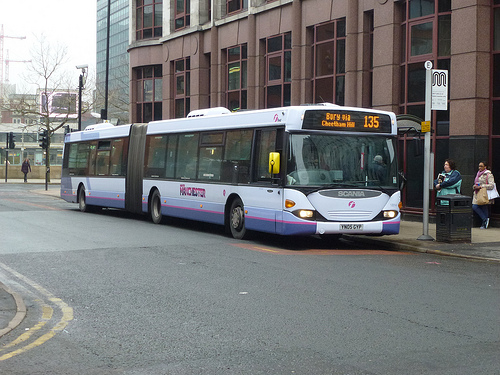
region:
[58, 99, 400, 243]
bus is stretched city bus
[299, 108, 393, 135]
bus has digital readout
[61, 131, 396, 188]
windows on bus reflecting surroundings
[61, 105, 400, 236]
white pink and purple bus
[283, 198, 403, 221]
two headlights lit on bus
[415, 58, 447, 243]
signpost has banner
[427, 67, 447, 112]
white banner with m on it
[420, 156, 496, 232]
people walking to bus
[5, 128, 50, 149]
black stoplights hang above street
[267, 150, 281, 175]
yellow side view mirror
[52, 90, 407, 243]
long bus on city street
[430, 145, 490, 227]
people standing on sidewalk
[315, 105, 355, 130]
destination on front of bus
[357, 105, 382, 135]
orange numbers on bus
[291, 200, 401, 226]
glowing headlights on bus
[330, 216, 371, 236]
license plate on front of bus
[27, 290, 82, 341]
yellow curved line in road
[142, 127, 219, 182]
windows on side of bus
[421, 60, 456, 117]
sign on metal pole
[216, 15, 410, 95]
windows on red building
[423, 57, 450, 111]
White Bus stop sign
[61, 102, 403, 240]
an extra long city bus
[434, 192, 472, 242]
a city trash receptacle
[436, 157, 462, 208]
a woman with dark hair standing by the bus stop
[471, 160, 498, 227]
a woman wearing a tan jacket and scarf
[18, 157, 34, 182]
a woman walking in the distance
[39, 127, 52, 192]
a traffic light in the distance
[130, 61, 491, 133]
a red brick building behind the bus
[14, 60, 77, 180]
a leafless tree in the background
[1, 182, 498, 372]
a city street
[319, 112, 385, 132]
digital route number sign on bus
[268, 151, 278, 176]
yellow mirror on bus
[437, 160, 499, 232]
two people waiting at bus stop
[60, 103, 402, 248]
purple and white double-length bus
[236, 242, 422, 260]
red bus lane marking in front of bus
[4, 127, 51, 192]
two traffic lights behind bus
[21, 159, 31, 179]
person walking behind the bus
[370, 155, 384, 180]
bus driver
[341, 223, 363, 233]
license plate on front of bus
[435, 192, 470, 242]
trash can at bus stop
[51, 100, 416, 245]
a bus park on side of road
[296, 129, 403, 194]
windshield of bus is large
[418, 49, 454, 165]
a pole with a sign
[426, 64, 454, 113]
a white sign on a pole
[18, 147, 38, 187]
a person walking on sidewalk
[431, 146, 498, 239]
two people in a bus stop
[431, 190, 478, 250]
trash can next to a pole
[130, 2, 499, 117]
a big building color red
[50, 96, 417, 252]
bus is white and purple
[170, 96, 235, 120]
vents on top of the bus